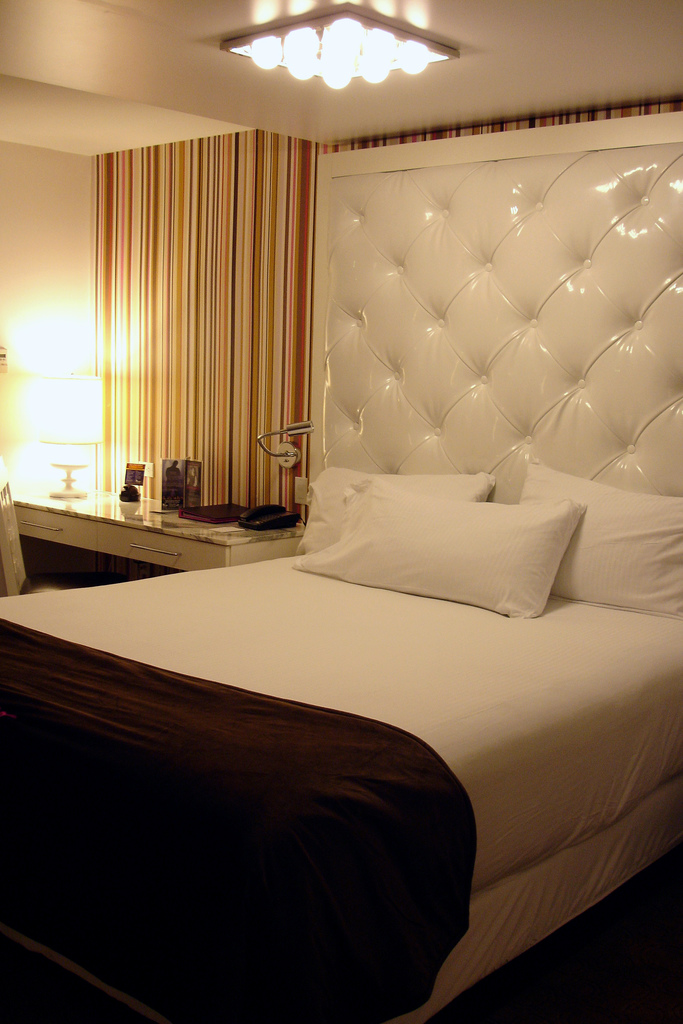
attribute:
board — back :
[315, 152, 658, 505]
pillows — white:
[281, 428, 657, 621]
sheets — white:
[1, 523, 659, 890]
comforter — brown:
[0, 614, 490, 995]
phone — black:
[199, 481, 302, 545]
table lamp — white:
[26, 370, 107, 504]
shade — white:
[31, 373, 107, 447]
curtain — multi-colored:
[89, 127, 319, 525]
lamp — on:
[27, 373, 102, 502]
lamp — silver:
[253, 418, 317, 467]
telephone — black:
[233, 500, 305, 531]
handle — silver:
[16, 517, 63, 531]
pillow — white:
[289, 474, 588, 621]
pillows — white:
[282, 449, 679, 622]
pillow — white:
[515, 457, 678, 622]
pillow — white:
[290, 461, 496, 558]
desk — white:
[17, 478, 301, 602]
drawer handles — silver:
[6, 504, 195, 568]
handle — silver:
[126, 539, 181, 565]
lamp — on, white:
[24, 369, 113, 503]